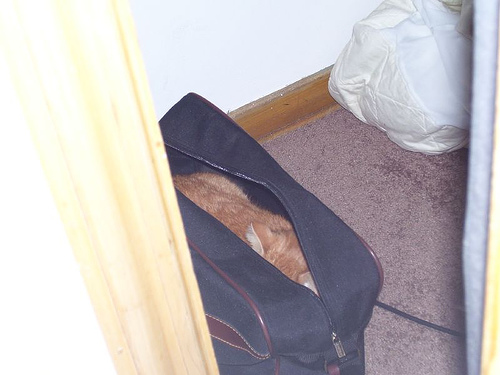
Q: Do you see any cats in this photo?
A: Yes, there is a cat.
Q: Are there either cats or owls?
A: Yes, there is a cat.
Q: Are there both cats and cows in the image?
A: No, there is a cat but no cows.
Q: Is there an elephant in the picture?
A: No, there are no elephants.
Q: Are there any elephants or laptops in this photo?
A: No, there are no elephants or laptops.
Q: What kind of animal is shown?
A: The animal is a cat.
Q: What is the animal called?
A: The animal is a cat.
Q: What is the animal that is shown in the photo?
A: The animal is a cat.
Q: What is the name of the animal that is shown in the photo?
A: The animal is a cat.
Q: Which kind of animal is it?
A: The animal is a cat.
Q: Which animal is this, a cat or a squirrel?
A: That is a cat.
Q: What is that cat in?
A: The cat is in the bag.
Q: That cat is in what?
A: The cat is in the bag.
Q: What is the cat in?
A: The cat is in the bag.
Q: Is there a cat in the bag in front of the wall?
A: Yes, there is a cat in the bag.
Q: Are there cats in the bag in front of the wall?
A: Yes, there is a cat in the bag.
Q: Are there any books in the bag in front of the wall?
A: No, there is a cat in the bag.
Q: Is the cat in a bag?
A: Yes, the cat is in a bag.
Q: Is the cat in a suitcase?
A: No, the cat is in a bag.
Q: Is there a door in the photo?
A: Yes, there is a door.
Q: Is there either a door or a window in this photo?
A: Yes, there is a door.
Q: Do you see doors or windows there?
A: Yes, there is a door.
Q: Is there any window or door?
A: Yes, there is a door.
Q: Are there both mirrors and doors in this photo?
A: No, there is a door but no mirrors.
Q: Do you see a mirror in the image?
A: No, there are no mirrors.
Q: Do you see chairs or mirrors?
A: No, there are no mirrors or chairs.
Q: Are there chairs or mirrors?
A: No, there are no mirrors or chairs.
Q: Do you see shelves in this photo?
A: No, there are no shelves.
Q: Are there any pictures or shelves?
A: No, there are no shelves or pictures.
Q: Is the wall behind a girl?
A: No, the wall is behind a bag.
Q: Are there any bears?
A: No, there are no bears.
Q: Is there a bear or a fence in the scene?
A: No, there are no bears or fences.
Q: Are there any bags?
A: Yes, there is a bag.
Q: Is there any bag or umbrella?
A: Yes, there is a bag.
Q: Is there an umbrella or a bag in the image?
A: Yes, there is a bag.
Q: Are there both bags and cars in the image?
A: No, there is a bag but no cars.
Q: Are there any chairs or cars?
A: No, there are no cars or chairs.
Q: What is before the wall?
A: The bag is in front of the wall.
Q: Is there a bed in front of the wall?
A: No, there is a bag in front of the wall.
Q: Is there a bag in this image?
A: Yes, there is a bag.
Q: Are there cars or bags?
A: Yes, there is a bag.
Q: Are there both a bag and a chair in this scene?
A: No, there is a bag but no chairs.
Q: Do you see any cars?
A: No, there are no cars.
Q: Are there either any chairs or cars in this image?
A: No, there are no cars or chairs.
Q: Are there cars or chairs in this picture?
A: No, there are no cars or chairs.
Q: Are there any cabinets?
A: No, there are no cabinets.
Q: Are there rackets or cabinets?
A: No, there are no cabinets or rackets.